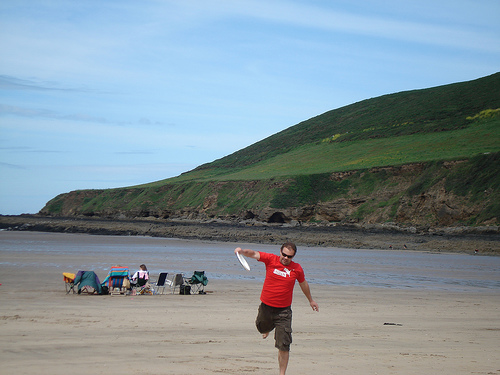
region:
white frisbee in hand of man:
[232, 249, 254, 276]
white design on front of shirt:
[264, 264, 299, 283]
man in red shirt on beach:
[233, 230, 332, 373]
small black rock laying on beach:
[376, 317, 421, 333]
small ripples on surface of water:
[14, 232, 76, 269]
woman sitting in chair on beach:
[129, 262, 153, 294]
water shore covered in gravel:
[309, 228, 471, 249]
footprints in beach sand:
[185, 339, 245, 373]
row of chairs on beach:
[150, 271, 215, 298]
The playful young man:
[234, 242, 319, 370]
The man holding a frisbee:
[236, 209, 319, 374]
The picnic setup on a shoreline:
[64, 263, 213, 298]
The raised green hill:
[41, 67, 498, 249]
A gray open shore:
[0, 230, 498, 372]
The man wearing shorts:
[236, 242, 319, 374]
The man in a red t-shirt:
[234, 239, 322, 374]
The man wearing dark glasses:
[235, 241, 320, 373]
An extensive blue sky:
[0, 0, 499, 216]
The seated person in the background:
[132, 264, 150, 294]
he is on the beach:
[222, 217, 329, 374]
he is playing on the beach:
[225, 213, 332, 370]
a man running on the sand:
[220, 223, 340, 370]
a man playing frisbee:
[222, 212, 319, 374]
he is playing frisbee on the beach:
[230, 219, 338, 373]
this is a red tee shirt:
[247, 238, 316, 316]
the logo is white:
[258, 257, 305, 281]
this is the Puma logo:
[268, 261, 295, 286]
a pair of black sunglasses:
[272, 242, 306, 262]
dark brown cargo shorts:
[248, 295, 298, 352]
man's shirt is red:
[235, 236, 319, 373]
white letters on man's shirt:
[271, 264, 289, 281]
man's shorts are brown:
[255, 300, 295, 352]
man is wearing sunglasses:
[278, 242, 297, 259]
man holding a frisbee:
[235, 238, 321, 373]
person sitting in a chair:
[131, 259, 150, 290]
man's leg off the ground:
[250, 303, 273, 343]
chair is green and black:
[184, 271, 209, 296]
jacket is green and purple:
[71, 262, 101, 297]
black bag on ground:
[177, 280, 194, 295]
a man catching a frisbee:
[224, 242, 331, 373]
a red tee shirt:
[252, 248, 307, 315]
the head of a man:
[274, 241, 299, 266]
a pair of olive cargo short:
[252, 299, 299, 356]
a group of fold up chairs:
[59, 262, 211, 303]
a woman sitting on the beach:
[125, 262, 150, 297]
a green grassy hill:
[199, 82, 495, 231]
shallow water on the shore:
[335, 251, 490, 302]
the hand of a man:
[306, 301, 323, 315]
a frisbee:
[227, 245, 254, 275]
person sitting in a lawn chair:
[130, 255, 150, 290]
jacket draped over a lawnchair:
[69, 266, 99, 297]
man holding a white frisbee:
[231, 233, 331, 367]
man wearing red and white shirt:
[232, 235, 337, 372]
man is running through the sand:
[217, 229, 328, 372]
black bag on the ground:
[175, 283, 192, 297]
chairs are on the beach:
[79, 268, 204, 300]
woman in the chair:
[129, 264, 148, 295]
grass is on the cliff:
[196, 177, 490, 230]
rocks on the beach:
[216, 209, 463, 250]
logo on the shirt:
[272, 267, 294, 280]